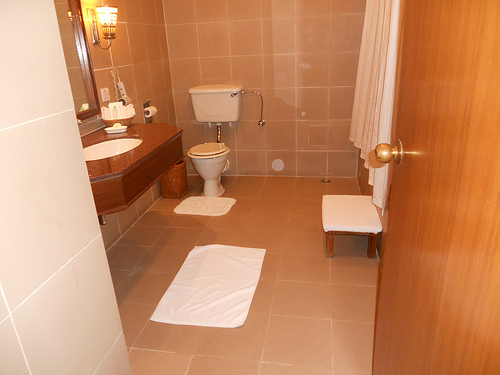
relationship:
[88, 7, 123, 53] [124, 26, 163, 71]
light on wall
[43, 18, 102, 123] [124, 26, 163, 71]
mirror on wall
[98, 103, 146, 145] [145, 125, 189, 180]
basket on counter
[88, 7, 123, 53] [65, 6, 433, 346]
light in bathroom